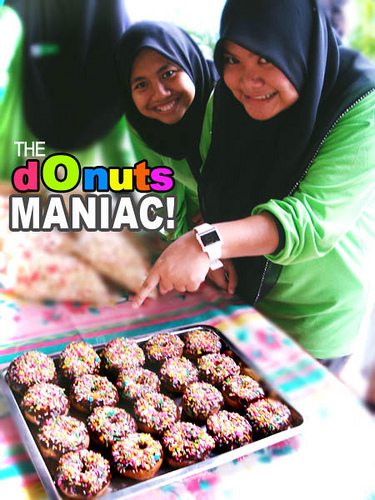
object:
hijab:
[197, 0, 373, 306]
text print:
[8, 193, 179, 232]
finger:
[131, 271, 160, 310]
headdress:
[115, 19, 220, 182]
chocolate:
[7, 327, 294, 499]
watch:
[193, 222, 224, 271]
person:
[0, 2, 149, 281]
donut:
[7, 330, 293, 499]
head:
[220, 1, 327, 122]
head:
[119, 19, 197, 125]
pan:
[1, 324, 309, 499]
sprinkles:
[61, 450, 109, 498]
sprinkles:
[104, 339, 145, 366]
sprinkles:
[111, 430, 160, 473]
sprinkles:
[228, 375, 265, 400]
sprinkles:
[47, 424, 78, 442]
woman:
[132, 0, 374, 395]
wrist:
[196, 223, 228, 260]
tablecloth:
[0, 293, 375, 499]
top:
[199, 85, 375, 361]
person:
[114, 19, 219, 242]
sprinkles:
[138, 394, 171, 425]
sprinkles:
[204, 409, 252, 440]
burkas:
[197, 0, 375, 308]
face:
[222, 40, 298, 121]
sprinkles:
[28, 381, 67, 419]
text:
[11, 152, 175, 194]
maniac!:
[8, 192, 177, 232]